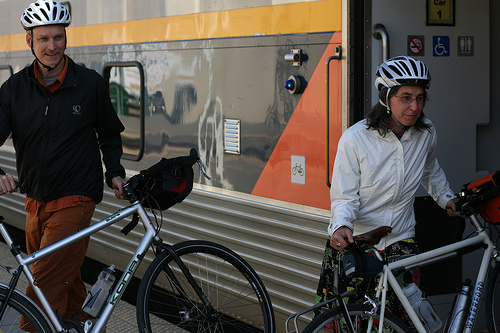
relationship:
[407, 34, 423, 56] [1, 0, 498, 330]
sign on bus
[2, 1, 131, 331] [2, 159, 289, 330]
man holding up bike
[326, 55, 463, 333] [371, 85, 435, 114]
woman wearing glasses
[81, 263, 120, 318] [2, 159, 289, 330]
bottle attached to bike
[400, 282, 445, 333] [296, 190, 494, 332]
bottle attached to bike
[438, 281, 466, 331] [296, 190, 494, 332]
bottle attached to bike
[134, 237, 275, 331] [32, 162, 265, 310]
wheel on bicycle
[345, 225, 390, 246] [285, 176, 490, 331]
seat on bicycle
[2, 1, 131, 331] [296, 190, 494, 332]
man holding bike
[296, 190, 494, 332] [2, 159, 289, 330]
bike holding bike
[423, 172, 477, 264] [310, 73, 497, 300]
bottle attached to bike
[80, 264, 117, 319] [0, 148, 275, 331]
bottle attached to bike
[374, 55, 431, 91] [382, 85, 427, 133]
cap on head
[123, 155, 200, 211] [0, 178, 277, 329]
bag on bike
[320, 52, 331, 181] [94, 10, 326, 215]
bar on bus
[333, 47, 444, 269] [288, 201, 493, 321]
woman holding bike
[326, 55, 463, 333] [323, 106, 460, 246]
woman wearing a jacket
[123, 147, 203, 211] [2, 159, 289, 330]
bag on a bike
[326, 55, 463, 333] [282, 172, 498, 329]
woman holding bike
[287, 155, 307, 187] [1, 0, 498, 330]
bike sign on bus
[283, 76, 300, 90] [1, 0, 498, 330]
blue light on bus